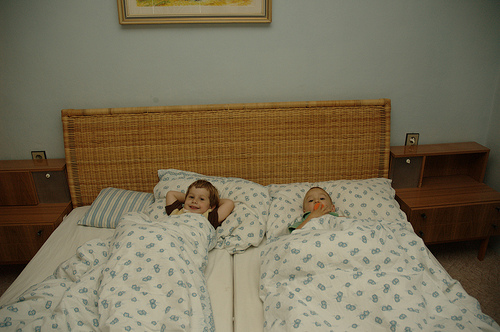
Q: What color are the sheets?
A: White.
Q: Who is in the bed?
A: Children.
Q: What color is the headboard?
A: Brown.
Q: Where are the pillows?
A: On bed.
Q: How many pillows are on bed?
A: Three.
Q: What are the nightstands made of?
A: Wood.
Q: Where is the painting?
A: Above headboard.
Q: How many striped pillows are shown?
A: One.